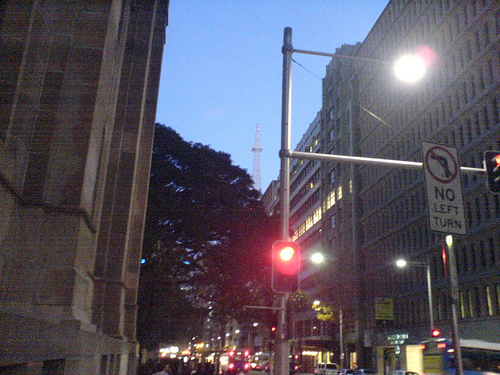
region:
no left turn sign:
[418, 137, 468, 234]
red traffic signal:
[270, 238, 303, 295]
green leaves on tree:
[140, 128, 277, 336]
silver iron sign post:
[440, 232, 463, 372]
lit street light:
[278, 22, 426, 374]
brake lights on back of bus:
[225, 348, 250, 371]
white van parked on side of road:
[311, 361, 339, 373]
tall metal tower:
[250, 118, 265, 195]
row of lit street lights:
[211, 321, 266, 341]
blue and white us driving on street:
[422, 337, 498, 372]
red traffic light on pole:
[255, 230, 310, 296]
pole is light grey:
[254, 43, 454, 373]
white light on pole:
[270, 51, 430, 113]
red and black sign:
[430, 130, 476, 252]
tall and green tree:
[151, 119, 273, 345]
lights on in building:
[280, 192, 347, 242]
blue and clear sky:
[185, 39, 260, 119]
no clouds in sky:
[158, 0, 245, 107]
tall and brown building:
[6, 0, 163, 347]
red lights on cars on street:
[220, 340, 272, 373]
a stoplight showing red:
[270, 239, 298, 295]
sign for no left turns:
[420, 141, 466, 236]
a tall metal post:
[273, 27, 293, 374]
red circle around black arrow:
[423, 143, 458, 185]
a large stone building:
[2, 0, 169, 374]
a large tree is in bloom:
[137, 121, 276, 374]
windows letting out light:
[289, 188, 346, 243]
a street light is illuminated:
[396, 257, 436, 333]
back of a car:
[219, 356, 248, 374]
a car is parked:
[315, 360, 342, 374]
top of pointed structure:
[249, 120, 268, 182]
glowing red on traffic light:
[272, 241, 299, 291]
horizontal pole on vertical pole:
[274, 47, 387, 240]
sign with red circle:
[422, 139, 467, 235]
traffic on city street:
[198, 348, 265, 372]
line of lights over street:
[199, 258, 407, 353]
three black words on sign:
[432, 185, 463, 230]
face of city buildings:
[279, 1, 498, 337]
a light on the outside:
[358, 6, 498, 107]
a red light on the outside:
[262, 231, 332, 276]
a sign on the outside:
[397, 141, 476, 266]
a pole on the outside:
[237, 66, 379, 367]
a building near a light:
[35, 96, 377, 327]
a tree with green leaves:
[141, 180, 243, 254]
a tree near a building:
[176, 141, 387, 241]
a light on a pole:
[346, 22, 459, 135]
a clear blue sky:
[204, 47, 267, 126]